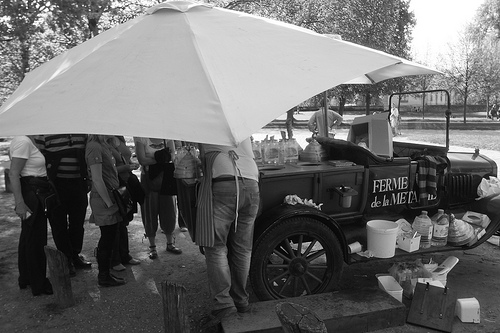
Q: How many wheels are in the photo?
A: One.